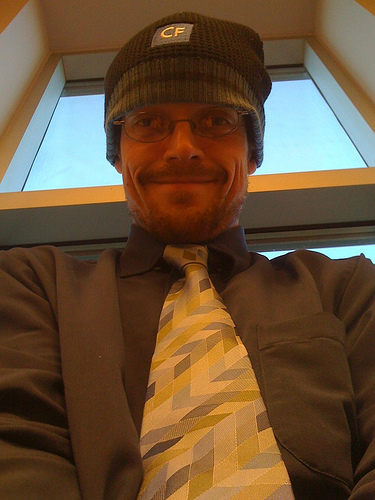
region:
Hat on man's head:
[94, 18, 276, 240]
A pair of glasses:
[108, 102, 252, 147]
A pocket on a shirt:
[249, 308, 365, 490]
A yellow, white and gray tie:
[137, 240, 294, 497]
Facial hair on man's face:
[114, 155, 249, 245]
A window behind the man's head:
[18, 60, 369, 193]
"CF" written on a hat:
[158, 24, 190, 43]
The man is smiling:
[99, 17, 274, 244]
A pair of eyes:
[131, 105, 232, 139]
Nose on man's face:
[163, 123, 202, 169]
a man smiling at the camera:
[0, 6, 373, 498]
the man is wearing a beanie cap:
[97, 12, 279, 242]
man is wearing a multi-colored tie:
[140, 241, 295, 499]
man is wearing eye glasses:
[95, 9, 288, 242]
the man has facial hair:
[91, 6, 281, 237]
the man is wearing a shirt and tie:
[2, 233, 370, 498]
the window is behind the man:
[0, 13, 374, 253]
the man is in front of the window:
[33, 41, 354, 235]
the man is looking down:
[30, 7, 366, 238]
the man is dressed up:
[2, 218, 368, 494]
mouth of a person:
[138, 168, 224, 193]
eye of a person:
[132, 113, 167, 133]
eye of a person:
[199, 111, 231, 132]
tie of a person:
[130, 239, 299, 498]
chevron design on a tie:
[175, 398, 220, 423]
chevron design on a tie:
[186, 428, 213, 464]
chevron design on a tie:
[209, 410, 239, 448]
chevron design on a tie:
[172, 351, 191, 379]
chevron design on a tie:
[147, 379, 173, 411]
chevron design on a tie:
[138, 429, 186, 461]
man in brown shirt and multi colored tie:
[1, 12, 373, 499]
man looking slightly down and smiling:
[2, 10, 374, 499]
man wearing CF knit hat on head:
[0, 12, 374, 497]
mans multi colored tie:
[136, 244, 292, 499]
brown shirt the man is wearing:
[2, 219, 373, 499]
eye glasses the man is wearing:
[105, 103, 254, 145]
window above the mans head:
[18, 66, 372, 194]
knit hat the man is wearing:
[95, 12, 276, 181]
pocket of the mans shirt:
[252, 310, 367, 485]